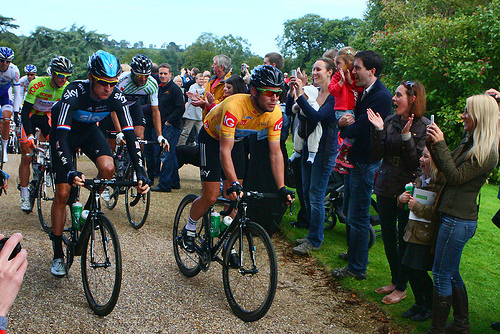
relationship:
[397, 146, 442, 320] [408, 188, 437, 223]
child holding book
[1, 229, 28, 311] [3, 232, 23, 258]
hand holding camera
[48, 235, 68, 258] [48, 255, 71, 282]
sock on foot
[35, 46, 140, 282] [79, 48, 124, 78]
man wearing helmet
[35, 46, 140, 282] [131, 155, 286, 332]
man riding bike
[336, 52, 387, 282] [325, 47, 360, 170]
man holding child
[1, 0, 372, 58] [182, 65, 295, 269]
sky above man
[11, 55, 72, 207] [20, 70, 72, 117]
man in top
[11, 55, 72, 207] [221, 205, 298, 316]
man riding bike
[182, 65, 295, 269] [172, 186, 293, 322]
man riding bike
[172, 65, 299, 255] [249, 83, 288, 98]
man wearing sunglasses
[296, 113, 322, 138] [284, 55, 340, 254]
sling attached to woman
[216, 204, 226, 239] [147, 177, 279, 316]
bottle attached to bike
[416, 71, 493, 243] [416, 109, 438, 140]
woman taking picture with cell phone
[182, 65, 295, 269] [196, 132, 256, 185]
man wearing shorts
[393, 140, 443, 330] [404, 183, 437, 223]
child holding book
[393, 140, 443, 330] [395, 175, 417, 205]
child holding bottle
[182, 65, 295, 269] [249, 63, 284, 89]
man wearing helmet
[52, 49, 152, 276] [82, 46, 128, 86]
man wearing helmet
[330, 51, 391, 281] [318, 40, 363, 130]
man holding girl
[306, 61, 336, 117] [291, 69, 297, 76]
woman looking at camera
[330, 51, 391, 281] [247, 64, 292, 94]
man with helmet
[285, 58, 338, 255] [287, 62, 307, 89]
woman holding camera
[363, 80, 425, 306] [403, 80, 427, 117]
woman with hair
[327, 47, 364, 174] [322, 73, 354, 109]
child with shirt